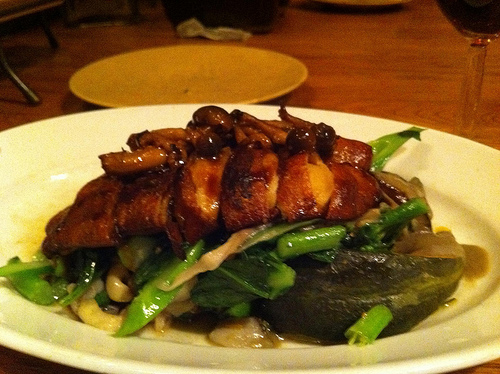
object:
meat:
[41, 104, 381, 261]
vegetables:
[0, 200, 428, 346]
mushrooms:
[99, 103, 333, 179]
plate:
[69, 44, 310, 108]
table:
[0, 0, 500, 374]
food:
[6, 103, 489, 347]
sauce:
[207, 310, 281, 349]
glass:
[436, 0, 500, 139]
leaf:
[58, 252, 97, 308]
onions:
[52, 254, 175, 330]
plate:
[0, 101, 500, 374]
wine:
[438, 0, 499, 37]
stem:
[458, 39, 488, 138]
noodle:
[67, 265, 132, 330]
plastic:
[176, 17, 253, 40]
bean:
[343, 304, 395, 344]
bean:
[275, 224, 350, 260]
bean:
[114, 258, 185, 338]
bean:
[0, 249, 95, 307]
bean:
[370, 125, 423, 166]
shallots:
[135, 239, 206, 287]